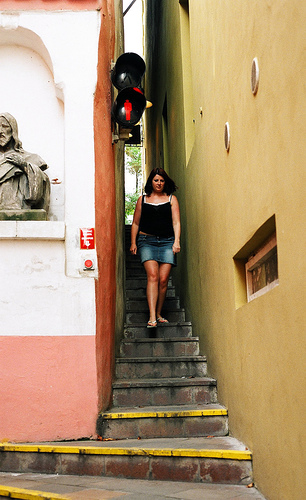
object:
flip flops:
[147, 319, 158, 328]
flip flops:
[157, 317, 169, 323]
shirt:
[138, 194, 174, 236]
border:
[140, 190, 173, 207]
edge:
[104, 411, 228, 417]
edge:
[1, 443, 251, 458]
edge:
[0, 484, 56, 497]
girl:
[130, 168, 181, 329]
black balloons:
[112, 52, 146, 89]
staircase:
[110, 310, 252, 500]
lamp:
[104, 53, 150, 146]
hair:
[144, 168, 179, 194]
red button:
[83, 259, 95, 271]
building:
[1, 0, 126, 444]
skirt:
[137, 232, 176, 265]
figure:
[0, 112, 51, 222]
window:
[2, 23, 63, 234]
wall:
[2, 3, 117, 451]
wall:
[158, 3, 299, 396]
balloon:
[111, 87, 153, 123]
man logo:
[124, 99, 132, 120]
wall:
[106, 1, 125, 407]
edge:
[99, 408, 228, 423]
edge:
[98, 448, 252, 461]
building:
[141, 2, 303, 499]